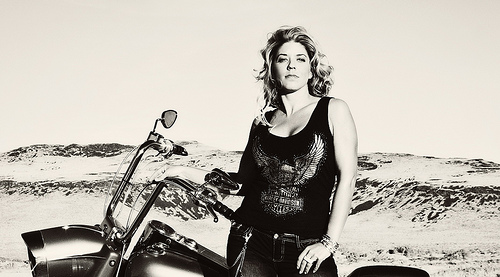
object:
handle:
[157, 140, 188, 156]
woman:
[225, 22, 356, 273]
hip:
[303, 234, 341, 263]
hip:
[226, 220, 253, 246]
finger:
[313, 257, 324, 273]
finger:
[299, 250, 313, 274]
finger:
[295, 247, 309, 269]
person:
[225, 23, 357, 277]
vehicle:
[18, 107, 430, 274]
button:
[273, 233, 279, 239]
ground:
[445, 148, 480, 177]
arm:
[323, 99, 360, 250]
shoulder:
[319, 95, 357, 127]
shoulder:
[247, 110, 274, 132]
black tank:
[238, 95, 336, 271]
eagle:
[248, 131, 327, 216]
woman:
[78, 45, 494, 230]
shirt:
[237, 105, 334, 236]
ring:
[303, 257, 310, 265]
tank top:
[235, 94, 334, 237]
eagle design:
[252, 132, 330, 216]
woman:
[219, 25, 380, 275]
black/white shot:
[1, 0, 500, 277]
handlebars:
[105, 109, 237, 240]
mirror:
[204, 166, 240, 190]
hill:
[9, 142, 496, 227]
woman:
[233, 24, 338, 275]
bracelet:
[321, 234, 342, 253]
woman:
[219, 22, 361, 208]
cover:
[18, 224, 108, 276]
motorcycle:
[20, 108, 430, 277]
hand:
[296, 242, 334, 273]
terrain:
[2, 132, 498, 274]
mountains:
[358, 145, 498, 267]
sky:
[0, 0, 500, 156]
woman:
[204, 24, 359, 274]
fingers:
[294, 245, 324, 275]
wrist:
[319, 231, 339, 252]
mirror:
[159, 109, 177, 129]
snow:
[22, 150, 220, 218]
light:
[19, 231, 46, 270]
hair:
[254, 25, 333, 109]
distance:
[0, 115, 500, 201]